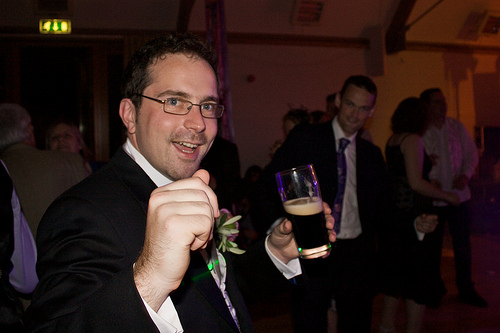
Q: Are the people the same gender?
A: No, they are both male and female.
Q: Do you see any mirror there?
A: No, there are no mirrors.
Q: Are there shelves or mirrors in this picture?
A: No, there are no mirrors or shelves.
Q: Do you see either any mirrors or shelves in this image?
A: No, there are no mirrors or shelves.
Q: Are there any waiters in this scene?
A: No, there are no waiters.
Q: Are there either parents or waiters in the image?
A: No, there are no waiters or parents.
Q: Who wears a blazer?
A: The man wears a blazer.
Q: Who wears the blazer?
A: The man wears a blazer.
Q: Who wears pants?
A: The man wears pants.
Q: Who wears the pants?
A: The man wears pants.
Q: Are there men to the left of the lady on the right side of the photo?
A: Yes, there is a man to the left of the lady.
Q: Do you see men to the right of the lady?
A: No, the man is to the left of the lady.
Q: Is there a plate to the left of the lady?
A: No, there is a man to the left of the lady.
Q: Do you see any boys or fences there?
A: No, there are no fences or boys.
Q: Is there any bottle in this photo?
A: No, there are no bottles.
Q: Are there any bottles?
A: No, there are no bottles.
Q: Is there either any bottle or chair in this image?
A: No, there are no bottles or chairs.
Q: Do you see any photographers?
A: No, there are no photographers.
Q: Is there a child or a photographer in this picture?
A: No, there are no photographers or children.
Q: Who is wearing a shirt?
A: The man is wearing a shirt.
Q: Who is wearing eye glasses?
A: The man is wearing eye glasses.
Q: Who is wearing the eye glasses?
A: The man is wearing eye glasses.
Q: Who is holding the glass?
A: The man is holding the glass.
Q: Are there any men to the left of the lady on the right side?
A: Yes, there is a man to the left of the lady.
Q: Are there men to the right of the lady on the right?
A: No, the man is to the left of the lady.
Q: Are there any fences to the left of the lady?
A: No, there is a man to the left of the lady.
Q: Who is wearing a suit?
A: The man is wearing a suit.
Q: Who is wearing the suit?
A: The man is wearing a suit.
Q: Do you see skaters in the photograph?
A: No, there are no skaters.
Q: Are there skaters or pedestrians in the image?
A: No, there are no skaters or pedestrians.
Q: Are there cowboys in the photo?
A: No, there are no cowboys.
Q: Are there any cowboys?
A: No, there are no cowboys.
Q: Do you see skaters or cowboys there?
A: No, there are no cowboys or skaters.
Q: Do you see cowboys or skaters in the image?
A: No, there are no cowboys or skaters.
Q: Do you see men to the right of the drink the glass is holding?
A: Yes, there is a man to the right of the beer.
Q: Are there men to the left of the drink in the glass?
A: No, the man is to the right of the beer.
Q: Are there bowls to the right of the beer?
A: No, there is a man to the right of the beer.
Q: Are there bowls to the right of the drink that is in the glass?
A: No, there is a man to the right of the beer.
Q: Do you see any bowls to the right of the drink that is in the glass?
A: No, there is a man to the right of the beer.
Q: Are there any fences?
A: No, there are no fences.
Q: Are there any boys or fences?
A: No, there are no fences or boys.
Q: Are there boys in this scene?
A: No, there are no boys.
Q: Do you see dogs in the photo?
A: No, there are no dogs.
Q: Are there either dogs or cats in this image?
A: No, there are no dogs or cats.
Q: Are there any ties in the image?
A: Yes, there is a tie.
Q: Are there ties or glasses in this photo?
A: Yes, there is a tie.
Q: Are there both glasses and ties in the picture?
A: Yes, there are both a tie and glasses.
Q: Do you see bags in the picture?
A: No, there are no bags.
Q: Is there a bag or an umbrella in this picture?
A: No, there are no bags or umbrellas.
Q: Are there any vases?
A: No, there are no vases.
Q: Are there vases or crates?
A: No, there are no vases or crates.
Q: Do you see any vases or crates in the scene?
A: No, there are no vases or crates.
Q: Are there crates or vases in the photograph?
A: No, there are no vases or crates.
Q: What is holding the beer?
A: The glass is holding the beer.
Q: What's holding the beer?
A: The glass is holding the beer.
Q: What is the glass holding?
A: The glass is holding the beer.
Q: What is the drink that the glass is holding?
A: The drink is beer.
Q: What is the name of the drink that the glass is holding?
A: The drink is beer.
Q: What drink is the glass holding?
A: The glass is holding the beer.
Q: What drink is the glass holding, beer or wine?
A: The glass is holding beer.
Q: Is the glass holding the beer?
A: Yes, the glass is holding the beer.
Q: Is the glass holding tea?
A: No, the glass is holding the beer.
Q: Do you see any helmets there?
A: No, there are no helmets.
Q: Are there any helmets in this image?
A: No, there are no helmets.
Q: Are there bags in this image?
A: No, there are no bags.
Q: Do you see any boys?
A: No, there are no boys.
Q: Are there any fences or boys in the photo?
A: No, there are no boys or fences.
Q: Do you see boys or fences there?
A: No, there are no boys or fences.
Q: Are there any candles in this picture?
A: No, there are no candles.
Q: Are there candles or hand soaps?
A: No, there are no candles or hand soaps.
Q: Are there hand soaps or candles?
A: No, there are no candles or hand soaps.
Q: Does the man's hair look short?
A: Yes, the hair is short.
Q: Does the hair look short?
A: Yes, the hair is short.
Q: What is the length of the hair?
A: The hair is short.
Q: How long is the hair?
A: The hair is short.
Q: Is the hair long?
A: No, the hair is short.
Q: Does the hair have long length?
A: No, the hair is short.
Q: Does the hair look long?
A: No, the hair is short.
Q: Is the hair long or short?
A: The hair is short.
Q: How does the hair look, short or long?
A: The hair is short.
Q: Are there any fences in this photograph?
A: No, there are no fences.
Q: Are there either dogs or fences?
A: No, there are no fences or dogs.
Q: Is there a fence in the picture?
A: No, there are no fences.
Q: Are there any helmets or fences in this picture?
A: No, there are no fences or helmets.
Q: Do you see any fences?
A: No, there are no fences.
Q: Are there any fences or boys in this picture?
A: No, there are no fences or boys.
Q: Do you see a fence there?
A: No, there are no fences.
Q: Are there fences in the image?
A: No, there are no fences.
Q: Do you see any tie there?
A: Yes, there is a tie.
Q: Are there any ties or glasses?
A: Yes, there is a tie.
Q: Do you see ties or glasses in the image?
A: Yes, there is a tie.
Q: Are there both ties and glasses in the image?
A: Yes, there are both a tie and glasses.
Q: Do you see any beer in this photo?
A: Yes, there is beer.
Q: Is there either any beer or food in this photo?
A: Yes, there is beer.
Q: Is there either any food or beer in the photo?
A: Yes, there is beer.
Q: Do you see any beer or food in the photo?
A: Yes, there is beer.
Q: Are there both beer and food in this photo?
A: No, there is beer but no food.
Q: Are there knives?
A: No, there are no knives.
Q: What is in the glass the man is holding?
A: The beer is in the glass.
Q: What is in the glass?
A: The beer is in the glass.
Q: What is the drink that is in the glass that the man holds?
A: The drink is beer.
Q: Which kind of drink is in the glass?
A: The drink is beer.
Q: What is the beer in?
A: The beer is in the glass.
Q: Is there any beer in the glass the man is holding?
A: Yes, there is beer in the glass.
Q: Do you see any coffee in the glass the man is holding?
A: No, there is beer in the glass.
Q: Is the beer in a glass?
A: Yes, the beer is in a glass.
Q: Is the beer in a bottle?
A: No, the beer is in a glass.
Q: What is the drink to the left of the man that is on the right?
A: The drink is beer.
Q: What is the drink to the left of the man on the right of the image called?
A: The drink is beer.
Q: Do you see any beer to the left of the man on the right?
A: Yes, there is beer to the left of the man.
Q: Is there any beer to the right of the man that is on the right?
A: No, the beer is to the left of the man.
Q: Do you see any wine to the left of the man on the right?
A: No, there is beer to the left of the man.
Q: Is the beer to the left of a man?
A: Yes, the beer is to the left of a man.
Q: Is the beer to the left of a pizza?
A: No, the beer is to the left of a man.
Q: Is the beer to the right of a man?
A: No, the beer is to the left of a man.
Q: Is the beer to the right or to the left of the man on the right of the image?
A: The beer is to the left of the man.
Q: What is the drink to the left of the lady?
A: The drink is beer.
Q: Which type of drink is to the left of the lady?
A: The drink is beer.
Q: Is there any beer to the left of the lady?
A: Yes, there is beer to the left of the lady.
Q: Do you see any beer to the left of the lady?
A: Yes, there is beer to the left of the lady.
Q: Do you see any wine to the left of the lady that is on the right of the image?
A: No, there is beer to the left of the lady.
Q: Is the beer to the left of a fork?
A: No, the beer is to the left of the lady.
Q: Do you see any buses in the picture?
A: No, there are no buses.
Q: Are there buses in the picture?
A: No, there are no buses.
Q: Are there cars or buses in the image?
A: No, there are no buses or cars.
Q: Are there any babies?
A: No, there are no babies.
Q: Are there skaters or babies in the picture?
A: No, there are no babies or skaters.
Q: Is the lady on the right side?
A: Yes, the lady is on the right of the image.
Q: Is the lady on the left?
A: No, the lady is on the right of the image.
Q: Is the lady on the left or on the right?
A: The lady is on the right of the image.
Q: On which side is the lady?
A: The lady is on the right of the image.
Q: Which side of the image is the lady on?
A: The lady is on the right of the image.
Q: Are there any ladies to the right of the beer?
A: Yes, there is a lady to the right of the beer.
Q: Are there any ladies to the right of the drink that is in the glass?
A: Yes, there is a lady to the right of the beer.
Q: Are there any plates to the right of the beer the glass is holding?
A: No, there is a lady to the right of the beer.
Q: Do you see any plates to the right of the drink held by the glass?
A: No, there is a lady to the right of the beer.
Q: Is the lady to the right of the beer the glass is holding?
A: Yes, the lady is to the right of the beer.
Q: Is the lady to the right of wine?
A: No, the lady is to the right of the beer.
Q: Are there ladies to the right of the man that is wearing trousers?
A: Yes, there is a lady to the right of the man.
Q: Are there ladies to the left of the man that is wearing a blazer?
A: No, the lady is to the right of the man.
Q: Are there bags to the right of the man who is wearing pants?
A: No, there is a lady to the right of the man.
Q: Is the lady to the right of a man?
A: Yes, the lady is to the right of a man.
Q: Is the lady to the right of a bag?
A: No, the lady is to the right of a man.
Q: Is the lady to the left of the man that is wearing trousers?
A: No, the lady is to the right of the man.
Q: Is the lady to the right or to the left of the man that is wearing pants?
A: The lady is to the right of the man.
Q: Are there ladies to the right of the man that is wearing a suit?
A: Yes, there is a lady to the right of the man.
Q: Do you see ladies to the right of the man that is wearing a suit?
A: Yes, there is a lady to the right of the man.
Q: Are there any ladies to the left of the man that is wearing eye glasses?
A: No, the lady is to the right of the man.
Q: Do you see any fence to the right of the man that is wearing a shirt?
A: No, there is a lady to the right of the man.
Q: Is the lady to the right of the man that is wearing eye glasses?
A: Yes, the lady is to the right of the man.